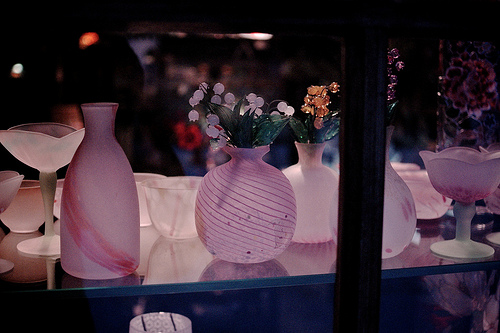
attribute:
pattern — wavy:
[224, 198, 289, 234]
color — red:
[61, 180, 124, 278]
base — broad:
[427, 232, 499, 260]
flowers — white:
[182, 78, 291, 148]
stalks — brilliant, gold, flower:
[297, 83, 339, 143]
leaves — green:
[233, 116, 269, 149]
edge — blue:
[74, 278, 293, 301]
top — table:
[1, 224, 493, 294]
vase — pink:
[418, 143, 499, 279]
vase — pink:
[277, 133, 338, 246]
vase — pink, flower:
[191, 140, 300, 265]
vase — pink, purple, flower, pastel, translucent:
[58, 100, 147, 284]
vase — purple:
[276, 135, 342, 253]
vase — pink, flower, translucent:
[2, 115, 86, 263]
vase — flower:
[268, 140, 346, 249]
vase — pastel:
[276, 140, 344, 241]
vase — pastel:
[184, 140, 299, 275]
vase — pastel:
[5, 122, 79, 265]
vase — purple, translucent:
[193, 140, 293, 271]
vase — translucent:
[265, 134, 346, 253]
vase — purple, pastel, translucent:
[408, 140, 495, 271]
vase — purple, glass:
[2, 122, 91, 262]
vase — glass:
[54, 101, 154, 277]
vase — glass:
[195, 145, 297, 275]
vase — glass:
[272, 139, 341, 243]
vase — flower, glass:
[419, 140, 498, 269]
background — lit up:
[6, 5, 498, 133]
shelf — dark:
[15, 241, 484, 305]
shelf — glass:
[4, 250, 493, 299]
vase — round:
[186, 143, 313, 267]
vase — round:
[267, 140, 339, 251]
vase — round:
[358, 150, 420, 260]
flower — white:
[186, 78, 210, 102]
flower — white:
[211, 80, 234, 110]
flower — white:
[246, 90, 266, 120]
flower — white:
[268, 90, 294, 125]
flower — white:
[200, 116, 220, 136]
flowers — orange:
[304, 84, 336, 125]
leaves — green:
[240, 117, 269, 142]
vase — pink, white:
[70, 100, 142, 271]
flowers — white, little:
[189, 77, 290, 142]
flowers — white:
[189, 80, 284, 145]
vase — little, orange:
[290, 151, 330, 225]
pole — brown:
[341, 103, 380, 273]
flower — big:
[444, 60, 484, 113]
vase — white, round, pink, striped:
[203, 160, 286, 258]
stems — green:
[231, 116, 262, 139]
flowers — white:
[191, 80, 243, 138]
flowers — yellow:
[294, 78, 333, 129]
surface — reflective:
[170, 241, 215, 274]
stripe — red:
[69, 200, 102, 258]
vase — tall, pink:
[72, 109, 137, 279]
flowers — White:
[182, 80, 286, 142]